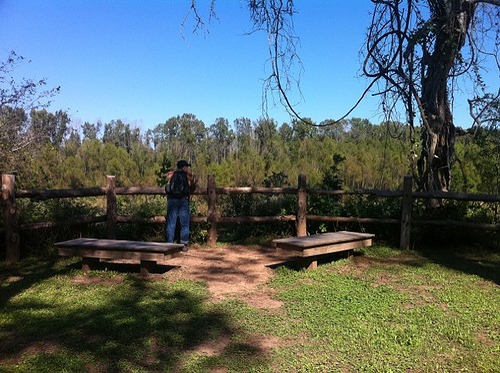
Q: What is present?
A: Trees.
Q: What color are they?
A: Green.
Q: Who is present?
A: A man.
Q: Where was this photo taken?
A: At a lookout point.